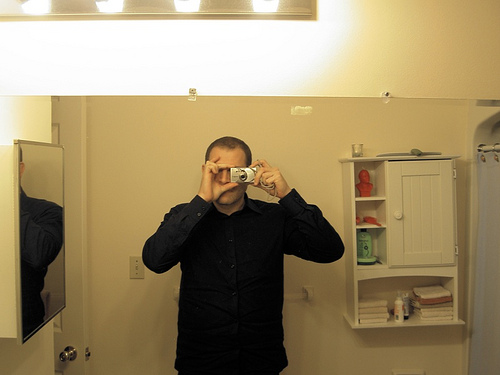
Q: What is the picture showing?
A: It is showing a bathroom.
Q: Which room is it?
A: It is a bathroom.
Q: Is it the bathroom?
A: Yes, it is the bathroom.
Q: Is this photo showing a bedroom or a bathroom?
A: It is showing a bathroom.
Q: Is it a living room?
A: No, it is a bathroom.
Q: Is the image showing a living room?
A: No, the picture is showing a bathroom.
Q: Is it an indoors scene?
A: Yes, it is indoors.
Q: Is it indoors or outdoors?
A: It is indoors.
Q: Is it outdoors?
A: No, it is indoors.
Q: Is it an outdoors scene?
A: No, it is indoors.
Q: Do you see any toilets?
A: No, there are no toilets.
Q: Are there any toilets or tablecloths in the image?
A: No, there are no toilets or tablecloths.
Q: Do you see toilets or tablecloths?
A: No, there are no toilets or tablecloths.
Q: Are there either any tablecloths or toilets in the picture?
A: No, there are no toilets or tablecloths.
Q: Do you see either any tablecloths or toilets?
A: No, there are no toilets or tablecloths.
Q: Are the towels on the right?
A: Yes, the towels are on the right of the image.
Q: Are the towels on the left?
A: No, the towels are on the right of the image.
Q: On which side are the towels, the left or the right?
A: The towels are on the right of the image.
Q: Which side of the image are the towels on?
A: The towels are on the right of the image.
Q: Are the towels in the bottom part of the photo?
A: Yes, the towels are in the bottom of the image.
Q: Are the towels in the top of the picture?
A: No, the towels are in the bottom of the image.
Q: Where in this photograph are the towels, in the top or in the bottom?
A: The towels are in the bottom of the image.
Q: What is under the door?
A: The towels are under the door.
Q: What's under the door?
A: The towels are under the door.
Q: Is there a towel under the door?
A: Yes, there are towels under the door.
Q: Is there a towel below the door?
A: Yes, there are towels below the door.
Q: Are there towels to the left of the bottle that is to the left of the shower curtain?
A: Yes, there are towels to the left of the bottle.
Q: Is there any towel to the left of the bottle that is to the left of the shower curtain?
A: Yes, there are towels to the left of the bottle.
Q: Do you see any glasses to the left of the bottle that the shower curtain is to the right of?
A: No, there are towels to the left of the bottle.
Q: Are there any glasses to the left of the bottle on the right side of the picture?
A: No, there are towels to the left of the bottle.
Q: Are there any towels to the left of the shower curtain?
A: Yes, there are towels to the left of the shower curtain.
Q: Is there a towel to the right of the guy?
A: Yes, there are towels to the right of the guy.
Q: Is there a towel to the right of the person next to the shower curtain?
A: Yes, there are towels to the right of the guy.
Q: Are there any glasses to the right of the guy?
A: No, there are towels to the right of the guy.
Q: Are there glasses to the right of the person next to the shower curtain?
A: No, there are towels to the right of the guy.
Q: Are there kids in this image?
A: No, there are no kids.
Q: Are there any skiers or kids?
A: No, there are no kids or skiers.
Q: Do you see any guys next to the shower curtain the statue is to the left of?
A: Yes, there is a guy next to the shower curtain.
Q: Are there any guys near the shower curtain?
A: Yes, there is a guy near the shower curtain.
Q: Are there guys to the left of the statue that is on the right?
A: Yes, there is a guy to the left of the statue.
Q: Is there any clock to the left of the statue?
A: No, there is a guy to the left of the statue.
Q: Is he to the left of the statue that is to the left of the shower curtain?
A: Yes, the guy is to the left of the statue.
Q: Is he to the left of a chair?
A: No, the guy is to the left of the statue.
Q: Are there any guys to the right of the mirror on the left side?
A: Yes, there is a guy to the right of the mirror.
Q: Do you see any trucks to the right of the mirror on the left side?
A: No, there is a guy to the right of the mirror.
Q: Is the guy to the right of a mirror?
A: Yes, the guy is to the right of a mirror.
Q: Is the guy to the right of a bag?
A: No, the guy is to the right of a mirror.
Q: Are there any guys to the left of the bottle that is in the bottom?
A: Yes, there is a guy to the left of the bottle.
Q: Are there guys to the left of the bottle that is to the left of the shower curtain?
A: Yes, there is a guy to the left of the bottle.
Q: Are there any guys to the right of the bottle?
A: No, the guy is to the left of the bottle.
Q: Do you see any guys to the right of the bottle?
A: No, the guy is to the left of the bottle.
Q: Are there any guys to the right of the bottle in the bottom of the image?
A: No, the guy is to the left of the bottle.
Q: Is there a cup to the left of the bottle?
A: No, there is a guy to the left of the bottle.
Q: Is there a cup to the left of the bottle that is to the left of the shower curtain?
A: No, there is a guy to the left of the bottle.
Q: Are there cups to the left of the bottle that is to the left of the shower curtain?
A: No, there is a guy to the left of the bottle.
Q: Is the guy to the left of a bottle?
A: Yes, the guy is to the left of a bottle.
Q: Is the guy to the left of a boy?
A: No, the guy is to the left of a bottle.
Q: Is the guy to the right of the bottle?
A: No, the guy is to the left of the bottle.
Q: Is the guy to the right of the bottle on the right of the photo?
A: No, the guy is to the left of the bottle.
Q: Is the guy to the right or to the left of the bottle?
A: The guy is to the left of the bottle.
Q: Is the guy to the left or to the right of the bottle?
A: The guy is to the left of the bottle.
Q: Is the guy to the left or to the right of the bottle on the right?
A: The guy is to the left of the bottle.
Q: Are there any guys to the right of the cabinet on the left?
A: Yes, there is a guy to the right of the cabinet.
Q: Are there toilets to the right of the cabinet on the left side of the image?
A: No, there is a guy to the right of the cabinet.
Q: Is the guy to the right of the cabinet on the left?
A: Yes, the guy is to the right of the cabinet.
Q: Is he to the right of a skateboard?
A: No, the guy is to the right of the cabinet.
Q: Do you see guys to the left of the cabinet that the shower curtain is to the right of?
A: Yes, there is a guy to the left of the cabinet.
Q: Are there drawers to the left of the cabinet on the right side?
A: No, there is a guy to the left of the cabinet.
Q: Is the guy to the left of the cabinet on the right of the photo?
A: Yes, the guy is to the left of the cabinet.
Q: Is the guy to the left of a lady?
A: No, the guy is to the left of the cabinet.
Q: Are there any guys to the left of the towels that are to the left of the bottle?
A: Yes, there is a guy to the left of the towels.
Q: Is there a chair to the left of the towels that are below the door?
A: No, there is a guy to the left of the towels.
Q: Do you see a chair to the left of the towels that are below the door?
A: No, there is a guy to the left of the towels.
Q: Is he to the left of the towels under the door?
A: Yes, the guy is to the left of the towels.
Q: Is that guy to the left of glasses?
A: No, the guy is to the left of the towels.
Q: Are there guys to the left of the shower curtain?
A: Yes, there is a guy to the left of the shower curtain.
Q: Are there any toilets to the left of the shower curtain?
A: No, there is a guy to the left of the shower curtain.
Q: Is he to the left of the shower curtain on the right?
A: Yes, the guy is to the left of the shower curtain.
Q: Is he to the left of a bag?
A: No, the guy is to the left of the shower curtain.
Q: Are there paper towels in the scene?
A: No, there are no paper towels.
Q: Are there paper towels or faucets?
A: No, there are no paper towels or faucets.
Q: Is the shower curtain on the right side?
A: Yes, the shower curtain is on the right of the image.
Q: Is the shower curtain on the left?
A: No, the shower curtain is on the right of the image.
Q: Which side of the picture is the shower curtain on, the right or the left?
A: The shower curtain is on the right of the image.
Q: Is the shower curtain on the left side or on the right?
A: The shower curtain is on the right of the image.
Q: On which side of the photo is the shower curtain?
A: The shower curtain is on the right of the image.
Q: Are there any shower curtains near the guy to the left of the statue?
A: Yes, there is a shower curtain near the guy.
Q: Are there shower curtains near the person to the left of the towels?
A: Yes, there is a shower curtain near the guy.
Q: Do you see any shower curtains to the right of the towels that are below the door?
A: Yes, there is a shower curtain to the right of the towels.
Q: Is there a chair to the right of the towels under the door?
A: No, there is a shower curtain to the right of the towels.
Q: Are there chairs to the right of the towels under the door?
A: No, there is a shower curtain to the right of the towels.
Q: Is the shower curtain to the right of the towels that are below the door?
A: Yes, the shower curtain is to the right of the towels.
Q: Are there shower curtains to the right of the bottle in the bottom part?
A: Yes, there is a shower curtain to the right of the bottle.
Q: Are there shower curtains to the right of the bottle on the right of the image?
A: Yes, there is a shower curtain to the right of the bottle.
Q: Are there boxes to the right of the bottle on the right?
A: No, there is a shower curtain to the right of the bottle.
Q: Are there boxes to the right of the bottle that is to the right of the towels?
A: No, there is a shower curtain to the right of the bottle.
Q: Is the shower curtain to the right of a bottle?
A: Yes, the shower curtain is to the right of a bottle.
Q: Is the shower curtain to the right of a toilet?
A: No, the shower curtain is to the right of a bottle.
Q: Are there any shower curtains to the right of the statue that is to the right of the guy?
A: Yes, there is a shower curtain to the right of the statue.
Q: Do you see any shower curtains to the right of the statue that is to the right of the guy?
A: Yes, there is a shower curtain to the right of the statue.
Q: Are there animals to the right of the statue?
A: No, there is a shower curtain to the right of the statue.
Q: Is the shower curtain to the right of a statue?
A: Yes, the shower curtain is to the right of a statue.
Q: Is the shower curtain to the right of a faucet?
A: No, the shower curtain is to the right of a statue.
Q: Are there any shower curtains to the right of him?
A: Yes, there is a shower curtain to the right of the guy.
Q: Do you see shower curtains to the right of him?
A: Yes, there is a shower curtain to the right of the guy.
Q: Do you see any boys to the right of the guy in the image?
A: No, there is a shower curtain to the right of the guy.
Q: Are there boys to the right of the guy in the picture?
A: No, there is a shower curtain to the right of the guy.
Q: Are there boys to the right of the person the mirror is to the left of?
A: No, there is a shower curtain to the right of the guy.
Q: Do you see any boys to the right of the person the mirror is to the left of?
A: No, there is a shower curtain to the right of the guy.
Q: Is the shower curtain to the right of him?
A: Yes, the shower curtain is to the right of a guy.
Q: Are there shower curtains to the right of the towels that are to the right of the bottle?
A: Yes, there is a shower curtain to the right of the towels.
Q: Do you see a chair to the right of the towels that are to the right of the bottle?
A: No, there is a shower curtain to the right of the towels.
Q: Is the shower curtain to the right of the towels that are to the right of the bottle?
A: Yes, the shower curtain is to the right of the towels.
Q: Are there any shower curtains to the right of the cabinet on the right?
A: Yes, there is a shower curtain to the right of the cabinet.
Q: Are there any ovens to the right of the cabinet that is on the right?
A: No, there is a shower curtain to the right of the cabinet.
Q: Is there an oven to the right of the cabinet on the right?
A: No, there is a shower curtain to the right of the cabinet.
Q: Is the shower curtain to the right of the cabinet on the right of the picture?
A: Yes, the shower curtain is to the right of the cabinet.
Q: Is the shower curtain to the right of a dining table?
A: No, the shower curtain is to the right of the cabinet.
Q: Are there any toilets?
A: No, there are no toilets.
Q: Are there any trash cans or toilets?
A: No, there are no toilets or trash cans.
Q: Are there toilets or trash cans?
A: No, there are no toilets or trash cans.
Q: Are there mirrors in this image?
A: Yes, there is a mirror.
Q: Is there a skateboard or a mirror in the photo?
A: Yes, there is a mirror.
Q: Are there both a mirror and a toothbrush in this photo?
A: No, there is a mirror but no toothbrushes.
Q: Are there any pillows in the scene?
A: No, there are no pillows.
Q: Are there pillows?
A: No, there are no pillows.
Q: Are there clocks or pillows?
A: No, there are no pillows or clocks.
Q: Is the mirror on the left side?
A: Yes, the mirror is on the left of the image.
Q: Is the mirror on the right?
A: No, the mirror is on the left of the image.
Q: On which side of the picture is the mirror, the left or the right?
A: The mirror is on the left of the image.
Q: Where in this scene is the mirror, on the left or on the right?
A: The mirror is on the left of the image.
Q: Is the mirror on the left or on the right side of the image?
A: The mirror is on the left of the image.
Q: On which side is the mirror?
A: The mirror is on the left of the image.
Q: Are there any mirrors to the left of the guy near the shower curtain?
A: Yes, there is a mirror to the left of the guy.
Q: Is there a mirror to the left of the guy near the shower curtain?
A: Yes, there is a mirror to the left of the guy.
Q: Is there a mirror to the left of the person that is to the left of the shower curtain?
A: Yes, there is a mirror to the left of the guy.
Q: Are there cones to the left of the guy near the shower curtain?
A: No, there is a mirror to the left of the guy.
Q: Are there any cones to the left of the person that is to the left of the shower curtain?
A: No, there is a mirror to the left of the guy.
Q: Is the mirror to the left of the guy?
A: Yes, the mirror is to the left of the guy.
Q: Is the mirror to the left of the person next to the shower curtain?
A: Yes, the mirror is to the left of the guy.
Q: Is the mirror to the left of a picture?
A: No, the mirror is to the left of the guy.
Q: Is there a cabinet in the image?
A: Yes, there is a cabinet.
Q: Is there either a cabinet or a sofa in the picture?
A: Yes, there is a cabinet.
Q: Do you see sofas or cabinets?
A: Yes, there is a cabinet.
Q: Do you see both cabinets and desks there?
A: No, there is a cabinet but no desks.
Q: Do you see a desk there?
A: No, there are no desks.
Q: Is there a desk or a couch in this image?
A: No, there are no desks or couches.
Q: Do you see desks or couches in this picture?
A: No, there are no desks or couches.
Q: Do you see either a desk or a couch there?
A: No, there are no desks or couches.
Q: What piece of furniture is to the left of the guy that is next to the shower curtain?
A: The piece of furniture is a cabinet.